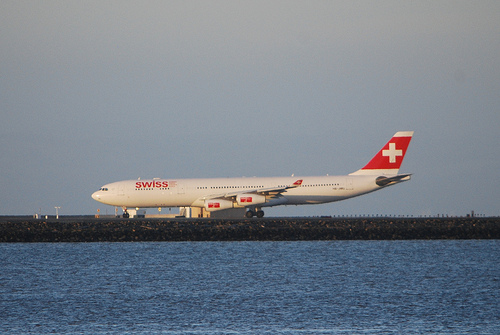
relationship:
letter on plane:
[136, 180, 169, 188] [51, 114, 431, 281]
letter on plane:
[135, 170, 172, 194] [89, 118, 494, 287]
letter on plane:
[136, 180, 169, 188] [53, 123, 453, 263]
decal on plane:
[184, 194, 230, 221] [83, 141, 417, 239]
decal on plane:
[230, 185, 289, 215] [84, 109, 483, 270]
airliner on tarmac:
[65, 117, 440, 226] [72, 210, 373, 238]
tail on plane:
[349, 131, 437, 192] [119, 141, 489, 264]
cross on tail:
[382, 142, 404, 163] [357, 120, 474, 203]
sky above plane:
[9, 24, 309, 174] [95, 98, 464, 240]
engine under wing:
[226, 186, 283, 210] [192, 164, 331, 212]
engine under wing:
[181, 188, 253, 232] [184, 189, 271, 231]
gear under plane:
[238, 204, 288, 229] [75, 115, 463, 258]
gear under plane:
[116, 194, 164, 239] [97, 99, 431, 197]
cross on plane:
[382, 142, 404, 163] [115, 127, 442, 220]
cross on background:
[380, 139, 405, 163] [377, 104, 422, 179]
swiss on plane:
[140, 179, 173, 199] [59, 121, 439, 256]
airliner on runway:
[90, 131, 414, 219] [67, 206, 188, 244]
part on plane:
[92, 175, 373, 207] [58, 96, 455, 212]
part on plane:
[92, 175, 373, 207] [58, 160, 376, 215]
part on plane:
[236, 208, 275, 228] [124, 137, 343, 245]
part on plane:
[228, 186, 266, 212] [94, 133, 376, 266]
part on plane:
[236, 193, 265, 206] [51, 141, 451, 286]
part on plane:
[377, 161, 414, 193] [124, 124, 395, 244]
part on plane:
[362, 129, 425, 190] [93, 115, 443, 267]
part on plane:
[143, 148, 359, 258] [67, 123, 364, 258]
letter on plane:
[136, 180, 169, 188] [93, 146, 412, 248]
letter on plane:
[136, 180, 169, 188] [91, 119, 412, 244]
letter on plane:
[136, 180, 169, 188] [97, 162, 383, 222]